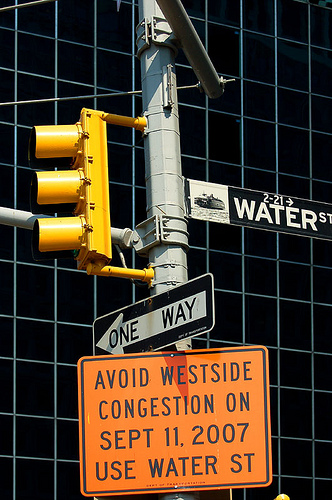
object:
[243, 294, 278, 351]
window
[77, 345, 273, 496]
sign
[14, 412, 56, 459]
window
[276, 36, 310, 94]
window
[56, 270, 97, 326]
window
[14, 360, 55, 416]
window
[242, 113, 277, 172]
window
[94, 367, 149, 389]
avoid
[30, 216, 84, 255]
signal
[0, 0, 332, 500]
building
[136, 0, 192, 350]
pole